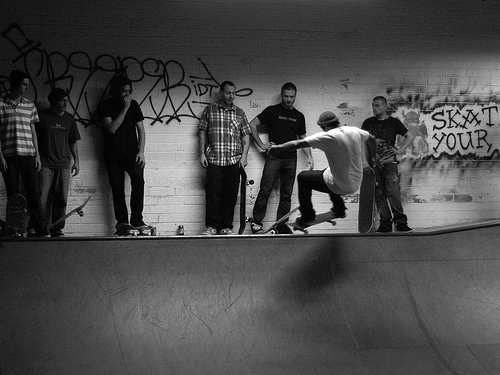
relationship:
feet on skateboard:
[291, 207, 348, 220] [296, 203, 344, 237]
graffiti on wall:
[2, 31, 259, 121] [2, 2, 498, 238]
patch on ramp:
[457, 326, 497, 370] [2, 224, 498, 362]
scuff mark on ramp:
[180, 274, 250, 340] [0, 217, 498, 370]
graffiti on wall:
[2, 31, 253, 127] [2, 2, 498, 238]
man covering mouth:
[93, 63, 163, 242] [123, 93, 133, 107]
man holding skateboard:
[198, 74, 263, 234] [234, 156, 259, 254]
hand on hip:
[391, 138, 406, 169] [373, 140, 408, 170]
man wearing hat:
[267, 101, 385, 242] [314, 109, 344, 137]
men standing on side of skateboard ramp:
[0, 56, 418, 237] [6, 214, 497, 372]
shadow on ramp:
[275, 225, 351, 315] [0, 217, 498, 370]